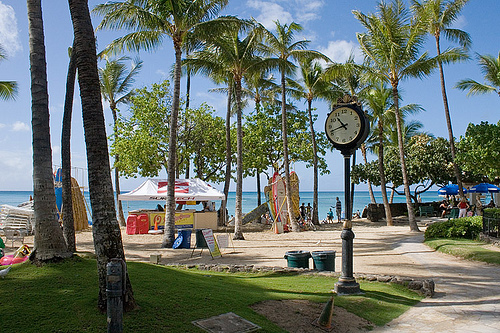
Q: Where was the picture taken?
A: A resort.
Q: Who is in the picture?
A: People.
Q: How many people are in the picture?
A: Five.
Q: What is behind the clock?
A: Buckets.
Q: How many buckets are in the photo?
A: Two.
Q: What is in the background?
A: The beach.